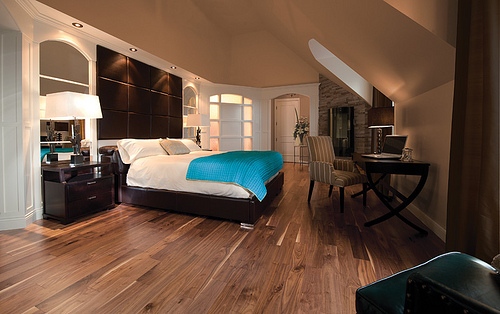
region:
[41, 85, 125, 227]
lamp with rectangular shade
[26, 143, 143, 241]
dark wooden night stand with drawers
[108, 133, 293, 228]
king-sized bed with white linens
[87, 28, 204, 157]
wooden rectangles mounted on a wall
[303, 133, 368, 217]
chair with striped upholstery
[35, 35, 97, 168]
tall mirror in the shape of an arch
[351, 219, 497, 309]
green leather chair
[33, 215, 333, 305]
hardwood floor comprised of long planks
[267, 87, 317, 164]
white door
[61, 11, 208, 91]
track lighting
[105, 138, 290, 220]
king size wood bed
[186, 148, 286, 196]
blue colored bedspread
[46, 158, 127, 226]
dark stained nightstand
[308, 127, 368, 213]
a striped wooden chair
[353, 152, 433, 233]
a long wooden coffee table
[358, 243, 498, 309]
a brown leather chair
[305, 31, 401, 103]
a skylight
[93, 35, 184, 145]
a decorative brown wall hanging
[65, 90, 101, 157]
a beautiful tall lamp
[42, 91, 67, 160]
the reflection of a nice lamp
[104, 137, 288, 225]
a queen size bed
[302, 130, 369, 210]
a chair with striped cushion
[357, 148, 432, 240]
a long wooden table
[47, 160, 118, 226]
a large wooden nightstand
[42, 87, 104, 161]
a nice looking table lamp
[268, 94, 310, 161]
the door from the bedroom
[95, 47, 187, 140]
a large wall decoration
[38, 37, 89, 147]
a shiny glass mirror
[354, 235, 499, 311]
a leather chair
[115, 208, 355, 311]
a stained wood floor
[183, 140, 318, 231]
BED SHEET IS LIGHT BLUE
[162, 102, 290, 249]
BED SHEET IS LIGHT BLUE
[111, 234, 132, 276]
FLOOR IS HARDWOOD OAK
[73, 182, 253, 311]
FLOOR IS HARDWOOD OAK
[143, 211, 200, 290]
FLOOR IS HARDWOOD OAK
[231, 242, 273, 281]
FLOOR IS HARDWOOD OAK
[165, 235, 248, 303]
FLOOR IS HARDWOOD OAK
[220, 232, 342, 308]
FLOOR IS HARDWOOD OAK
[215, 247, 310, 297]
FLOOR IS HARDWOOD OAK